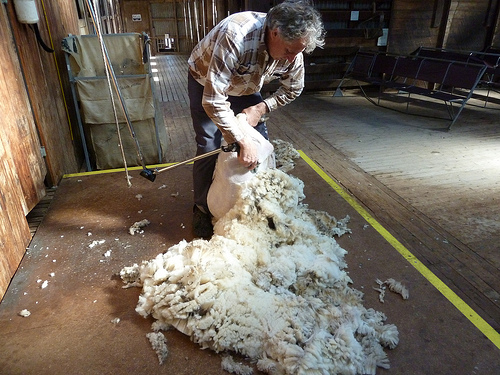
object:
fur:
[210, 247, 257, 268]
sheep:
[205, 152, 268, 225]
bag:
[60, 33, 167, 175]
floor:
[370, 127, 391, 151]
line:
[353, 206, 364, 210]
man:
[186, 1, 326, 241]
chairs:
[331, 52, 493, 130]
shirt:
[186, 13, 310, 144]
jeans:
[186, 70, 269, 215]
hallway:
[159, 48, 186, 102]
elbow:
[202, 98, 213, 109]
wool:
[207, 309, 245, 340]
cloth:
[137, 61, 145, 70]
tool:
[253, 169, 258, 173]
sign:
[351, 10, 359, 21]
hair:
[295, 17, 309, 32]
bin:
[83, 77, 153, 124]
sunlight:
[420, 152, 451, 169]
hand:
[241, 105, 267, 127]